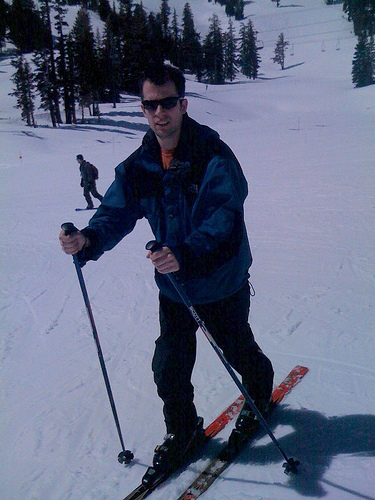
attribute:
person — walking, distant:
[55, 61, 275, 467]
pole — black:
[58, 221, 136, 465]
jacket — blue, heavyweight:
[81, 123, 249, 299]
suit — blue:
[79, 127, 250, 299]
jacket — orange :
[48, 62, 329, 403]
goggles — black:
[139, 92, 184, 113]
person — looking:
[49, 57, 298, 473]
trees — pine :
[9, 0, 289, 126]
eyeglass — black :
[131, 93, 186, 116]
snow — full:
[2, 0, 373, 499]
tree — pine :
[64, 12, 105, 114]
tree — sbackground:
[48, 14, 311, 112]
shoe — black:
[151, 429, 189, 469]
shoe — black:
[235, 403, 255, 428]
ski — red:
[95, 359, 305, 498]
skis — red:
[211, 383, 293, 427]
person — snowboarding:
[58, 140, 118, 217]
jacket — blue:
[102, 138, 247, 307]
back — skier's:
[83, 160, 106, 187]